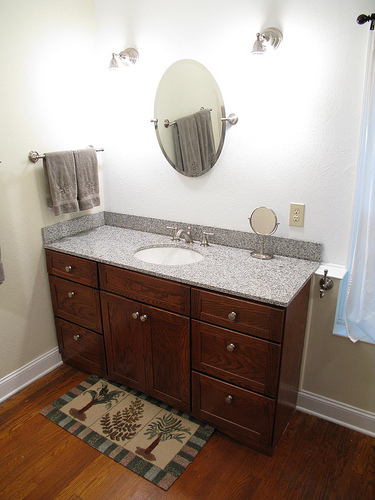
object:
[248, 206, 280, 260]
mirror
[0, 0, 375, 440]
wall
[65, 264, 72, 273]
knob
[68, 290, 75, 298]
knob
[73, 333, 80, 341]
knob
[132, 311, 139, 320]
knob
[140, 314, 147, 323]
knob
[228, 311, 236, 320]
knob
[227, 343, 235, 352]
knob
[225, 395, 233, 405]
knob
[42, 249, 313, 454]
cabinet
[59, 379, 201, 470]
pattern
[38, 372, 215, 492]
rug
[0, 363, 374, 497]
floor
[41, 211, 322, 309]
countertop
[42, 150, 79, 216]
towels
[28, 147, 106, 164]
rack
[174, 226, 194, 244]
faucet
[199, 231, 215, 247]
handles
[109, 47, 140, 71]
lights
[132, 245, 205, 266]
sink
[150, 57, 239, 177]
mirror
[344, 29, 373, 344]
curtain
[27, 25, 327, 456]
vanity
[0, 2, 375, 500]
bathroom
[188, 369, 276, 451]
drawer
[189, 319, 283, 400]
drawer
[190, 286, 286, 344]
drawer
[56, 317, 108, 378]
drawer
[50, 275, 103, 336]
drawer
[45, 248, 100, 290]
drawer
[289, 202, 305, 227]
outlet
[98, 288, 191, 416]
double doors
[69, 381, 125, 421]
palm tree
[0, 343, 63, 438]
baseboards